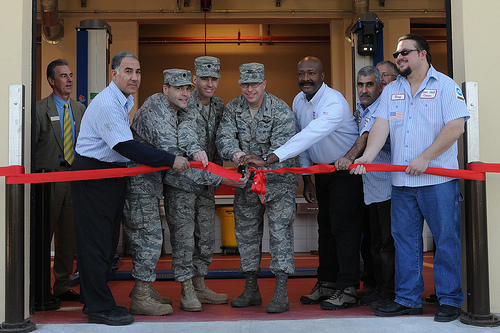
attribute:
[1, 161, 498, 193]
ribbon — cutting, ceremony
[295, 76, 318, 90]
mustache — black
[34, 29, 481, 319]
employess — group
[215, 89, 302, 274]
uniform — comouflauge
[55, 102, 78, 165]
tie — yellow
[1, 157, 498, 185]
ribbon — red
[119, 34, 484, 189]
guys — blue collar workers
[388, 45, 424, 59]
shades — cool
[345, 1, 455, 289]
guy — regular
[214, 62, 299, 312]
man — army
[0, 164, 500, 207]
ribbon — red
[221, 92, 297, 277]
uniform — comouflauge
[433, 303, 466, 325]
shoe — dress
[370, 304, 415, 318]
shoe — dress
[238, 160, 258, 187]
scissors — used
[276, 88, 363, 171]
shirt — white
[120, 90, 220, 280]
uniform — comouflauge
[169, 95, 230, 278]
uniform — comouflauge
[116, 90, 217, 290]
uniform — comouflauge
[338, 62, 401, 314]
guys — blue collar workers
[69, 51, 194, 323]
guys — blue collar workers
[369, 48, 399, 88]
guys — blue collar workers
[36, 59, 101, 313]
guys — civilian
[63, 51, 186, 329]
guys — civilian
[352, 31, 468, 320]
guys — civilian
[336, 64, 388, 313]
guys — civilian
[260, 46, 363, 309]
guys — civilian, blue collar workers